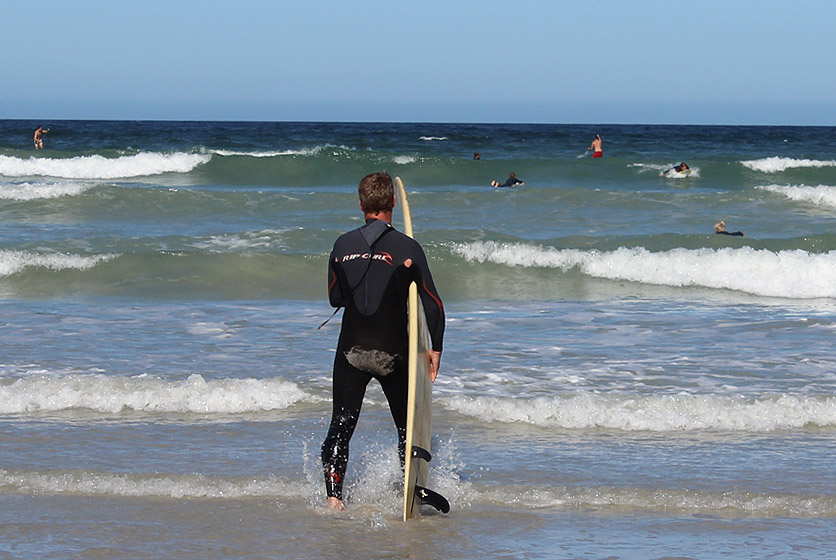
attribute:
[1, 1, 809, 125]
sky — blue, clear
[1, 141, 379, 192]
wave — white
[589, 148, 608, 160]
shorts — red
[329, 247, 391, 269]
letters — white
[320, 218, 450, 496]
wet suit — black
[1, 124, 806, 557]
water — blue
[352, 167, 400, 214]
hair — brown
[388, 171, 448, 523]
surfboard — white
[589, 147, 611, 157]
shorts — red